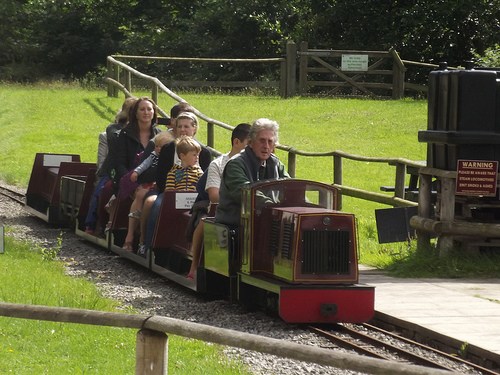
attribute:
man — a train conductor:
[216, 118, 307, 225]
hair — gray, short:
[249, 117, 279, 146]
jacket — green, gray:
[216, 150, 301, 220]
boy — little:
[162, 136, 205, 192]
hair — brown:
[175, 136, 202, 159]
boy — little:
[129, 132, 176, 182]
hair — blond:
[154, 131, 177, 148]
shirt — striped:
[134, 151, 162, 172]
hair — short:
[175, 111, 199, 137]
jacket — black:
[155, 140, 212, 194]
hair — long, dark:
[129, 97, 158, 132]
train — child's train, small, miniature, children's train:
[22, 152, 375, 326]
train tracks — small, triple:
[303, 322, 499, 372]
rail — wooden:
[0, 303, 458, 373]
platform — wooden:
[358, 276, 500, 370]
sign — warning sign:
[374, 206, 423, 253]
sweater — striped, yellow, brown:
[166, 163, 204, 193]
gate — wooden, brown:
[296, 44, 402, 102]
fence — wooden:
[105, 40, 499, 261]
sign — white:
[339, 53, 367, 73]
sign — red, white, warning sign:
[454, 156, 499, 200]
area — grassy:
[1, 85, 432, 274]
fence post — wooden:
[332, 153, 343, 209]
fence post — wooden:
[286, 150, 296, 178]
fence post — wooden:
[206, 121, 216, 148]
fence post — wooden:
[150, 81, 159, 107]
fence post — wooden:
[125, 70, 133, 99]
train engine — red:
[240, 177, 377, 323]